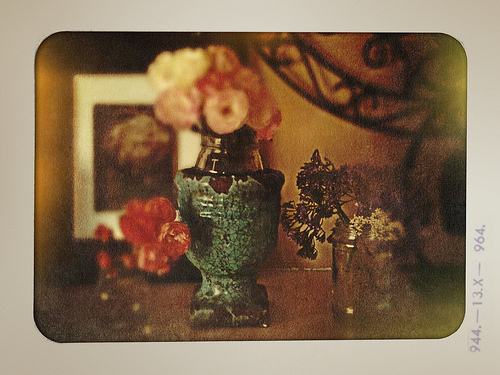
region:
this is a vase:
[166, 145, 297, 344]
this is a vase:
[307, 180, 415, 330]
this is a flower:
[121, 190, 191, 276]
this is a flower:
[196, 85, 257, 141]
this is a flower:
[107, 118, 167, 160]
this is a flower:
[150, 48, 220, 82]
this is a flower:
[226, 68, 282, 137]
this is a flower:
[341, 205, 408, 269]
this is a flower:
[290, 138, 351, 214]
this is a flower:
[281, 195, 333, 274]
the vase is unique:
[151, 165, 351, 325]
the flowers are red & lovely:
[94, 195, 194, 327]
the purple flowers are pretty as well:
[283, 145, 408, 325]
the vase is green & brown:
[183, 171, 290, 332]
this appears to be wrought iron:
[274, 41, 441, 136]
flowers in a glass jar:
[278, 148, 440, 324]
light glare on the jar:
[343, 241, 353, 248]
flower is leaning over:
[276, 191, 341, 261]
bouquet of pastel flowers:
[145, 40, 285, 161]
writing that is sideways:
[467, 218, 495, 367]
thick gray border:
[0, 1, 499, 371]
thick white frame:
[68, 63, 224, 249]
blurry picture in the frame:
[91, 107, 180, 211]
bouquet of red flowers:
[117, 195, 191, 276]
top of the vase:
[185, 119, 269, 170]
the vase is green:
[184, 170, 271, 312]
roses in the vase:
[157, 69, 264, 171]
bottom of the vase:
[151, 257, 274, 325]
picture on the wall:
[90, 77, 183, 237]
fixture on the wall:
[270, 47, 443, 142]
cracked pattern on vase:
[197, 236, 254, 274]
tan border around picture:
[142, 276, 481, 338]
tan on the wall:
[292, 137, 384, 169]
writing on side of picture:
[472, 209, 487, 360]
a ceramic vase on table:
[117, 148, 320, 335]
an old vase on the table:
[159, 146, 334, 332]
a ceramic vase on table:
[132, 133, 370, 350]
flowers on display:
[96, 52, 336, 292]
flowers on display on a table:
[125, 58, 317, 246]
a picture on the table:
[57, 47, 233, 265]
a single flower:
[78, 183, 231, 373]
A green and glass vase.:
[138, 48, 292, 333]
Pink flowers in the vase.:
[144, 45, 286, 152]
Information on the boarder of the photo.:
[466, 217, 486, 364]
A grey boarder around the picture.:
[8, 10, 498, 358]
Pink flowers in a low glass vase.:
[79, 195, 194, 331]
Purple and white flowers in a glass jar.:
[282, 151, 411, 322]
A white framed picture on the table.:
[66, 71, 206, 261]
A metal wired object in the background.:
[262, 41, 460, 147]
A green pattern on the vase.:
[173, 170, 292, 331]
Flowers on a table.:
[80, 51, 463, 317]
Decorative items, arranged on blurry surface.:
[3, 7, 495, 371]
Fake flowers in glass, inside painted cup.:
[152, 43, 274, 327]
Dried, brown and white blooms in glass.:
[290, 156, 412, 323]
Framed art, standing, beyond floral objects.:
[68, 69, 214, 265]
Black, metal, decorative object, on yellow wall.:
[272, 41, 461, 153]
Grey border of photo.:
[4, 3, 34, 333]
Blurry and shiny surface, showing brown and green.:
[301, 282, 449, 337]